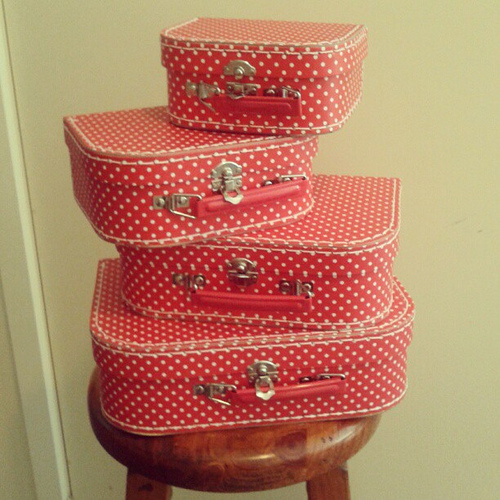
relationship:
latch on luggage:
[219, 250, 257, 282] [108, 178, 406, 324]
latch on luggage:
[242, 351, 278, 407] [89, 251, 423, 437]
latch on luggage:
[150, 180, 203, 210] [56, 99, 321, 259]